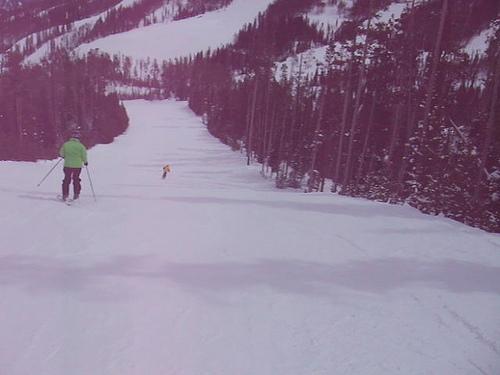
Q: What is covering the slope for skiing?
A: Snow.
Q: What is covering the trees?
A: Snow.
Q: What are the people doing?
A: Skiing.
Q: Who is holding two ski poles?
A: Person in green jacket.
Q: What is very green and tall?
A: The trees.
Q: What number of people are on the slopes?
A: Two.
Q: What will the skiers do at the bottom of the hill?
A: Have a hot drink.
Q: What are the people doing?
A: Skiing downhill.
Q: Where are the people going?
A: Skiing down the slope.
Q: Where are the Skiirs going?
A: Down the mountain.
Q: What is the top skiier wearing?
A: A green jacket.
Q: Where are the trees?
A: Between the slope.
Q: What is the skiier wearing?
A: A green jacket and black pants.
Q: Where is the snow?
A: On the ground and trees.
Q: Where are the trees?
A: Lining the slope.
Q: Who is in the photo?
A: Two people.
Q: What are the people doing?
A: Skiing.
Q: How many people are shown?
A: Two.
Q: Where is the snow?
A: On the ground.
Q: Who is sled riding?
A: No one.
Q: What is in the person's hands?
A: Poles.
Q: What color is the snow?
A: White.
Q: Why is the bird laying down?
A: No bird.